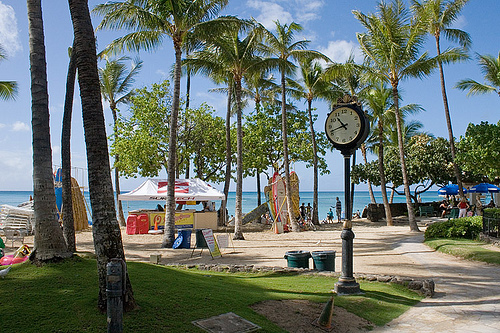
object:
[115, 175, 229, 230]
stand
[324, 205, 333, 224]
people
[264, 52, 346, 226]
trees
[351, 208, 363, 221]
people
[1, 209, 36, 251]
chairs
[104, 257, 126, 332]
pump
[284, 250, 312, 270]
cans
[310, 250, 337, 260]
bags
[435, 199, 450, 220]
people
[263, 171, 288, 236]
boards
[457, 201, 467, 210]
shirt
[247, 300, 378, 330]
bricks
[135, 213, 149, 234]
box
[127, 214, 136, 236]
box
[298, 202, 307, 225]
people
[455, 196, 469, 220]
lady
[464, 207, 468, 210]
hands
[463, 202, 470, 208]
hips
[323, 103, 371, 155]
clock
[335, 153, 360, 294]
pole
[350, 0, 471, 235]
tree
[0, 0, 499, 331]
park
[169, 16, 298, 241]
trees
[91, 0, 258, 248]
trees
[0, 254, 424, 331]
grass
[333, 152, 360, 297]
stand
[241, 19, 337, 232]
trees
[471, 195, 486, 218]
people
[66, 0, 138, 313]
trunk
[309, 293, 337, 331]
cone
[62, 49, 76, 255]
tree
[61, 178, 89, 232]
surfboards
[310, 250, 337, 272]
cans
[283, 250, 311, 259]
bags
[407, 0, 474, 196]
tree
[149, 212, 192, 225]
sign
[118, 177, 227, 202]
tarp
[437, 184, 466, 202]
umbrella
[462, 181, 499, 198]
umbrella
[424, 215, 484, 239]
bushes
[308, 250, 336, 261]
lid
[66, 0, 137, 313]
tree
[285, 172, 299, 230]
surfboard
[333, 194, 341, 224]
man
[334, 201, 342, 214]
shirt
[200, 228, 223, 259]
folding sign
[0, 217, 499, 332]
sidewalk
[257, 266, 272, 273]
rock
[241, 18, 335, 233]
palm tree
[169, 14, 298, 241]
palm tree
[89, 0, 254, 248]
palm tree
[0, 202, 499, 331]
beach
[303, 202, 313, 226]
person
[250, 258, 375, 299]
dirt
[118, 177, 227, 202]
canopy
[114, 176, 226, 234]
tent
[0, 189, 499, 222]
ocean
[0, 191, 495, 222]
water